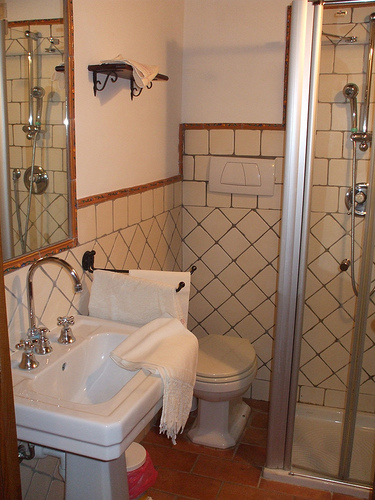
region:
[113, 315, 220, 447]
A towel on the edge of the sink.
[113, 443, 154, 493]
A garbage bin.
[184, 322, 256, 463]
A toilet.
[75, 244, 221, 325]
A towel rack attached to the wall.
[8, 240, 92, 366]
A metal faucet and knobs.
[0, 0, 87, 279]
A mirror with a wood frame.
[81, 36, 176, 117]
A small shelf with a towel on it.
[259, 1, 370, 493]
A shower stall.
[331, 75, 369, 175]
The shower head.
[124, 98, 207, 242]
The wall is partially tiled.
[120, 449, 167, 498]
red bag in trash can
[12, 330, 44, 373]
silver hot water handle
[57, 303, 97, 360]
silver cold water handle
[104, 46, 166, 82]
folded white wash cloths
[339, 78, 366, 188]
silver handheld water nozzle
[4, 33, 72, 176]
reflective mirror above sink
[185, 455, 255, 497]
rust colored floor tile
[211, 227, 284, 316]
white colored wall tile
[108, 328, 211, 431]
towel located on sink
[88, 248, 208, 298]
two towel holders under the towels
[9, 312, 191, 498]
the white bathroom sink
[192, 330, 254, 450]
the toilet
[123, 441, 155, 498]
the trash can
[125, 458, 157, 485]
the pink bag in the trash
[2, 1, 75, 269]
the bathroom mirror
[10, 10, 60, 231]
the reflection in the mirror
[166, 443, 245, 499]
the tiled bathroom floor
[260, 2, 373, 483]
the standing shower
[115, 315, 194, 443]
the towel hanging on the sink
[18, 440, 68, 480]
the pipes under the sink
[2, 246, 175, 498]
pedestal bathroom sink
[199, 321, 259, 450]
white porcelain toilet with seat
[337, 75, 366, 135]
shower head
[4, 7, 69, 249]
mirror with reflection of shower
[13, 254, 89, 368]
bathroom sink faucet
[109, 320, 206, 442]
white hand towel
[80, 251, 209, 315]
towel rack with two white towels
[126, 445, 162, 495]
small trashcan with red trashbag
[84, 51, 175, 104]
shelf with a white hand towel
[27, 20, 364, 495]
bathroom sink, toilet and shower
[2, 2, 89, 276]
mirror frame is brown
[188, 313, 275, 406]
toilet seat and lid are down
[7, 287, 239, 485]
bathroom sink is white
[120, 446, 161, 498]
trash can is white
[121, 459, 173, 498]
trash bag is red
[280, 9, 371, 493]
shower has glass doors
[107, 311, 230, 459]
white towel on sink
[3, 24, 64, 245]
reflection of shower head in mirror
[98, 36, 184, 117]
towel on shelf attached to wall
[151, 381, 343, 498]
the floor is tiled